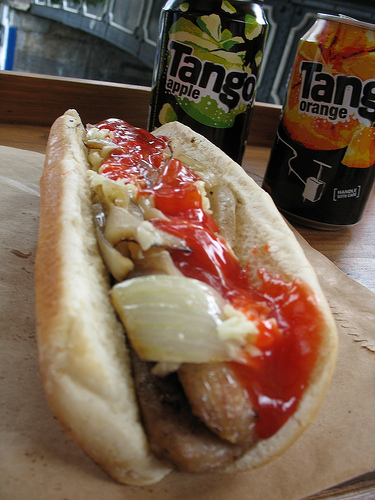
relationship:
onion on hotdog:
[111, 274, 259, 362] [32, 108, 338, 488]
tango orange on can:
[296, 57, 363, 124] [270, 10, 354, 245]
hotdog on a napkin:
[32, 102, 344, 488] [323, 251, 357, 482]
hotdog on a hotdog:
[32, 108, 338, 488] [32, 108, 338, 488]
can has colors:
[145, 0, 266, 162] [148, 29, 246, 133]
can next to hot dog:
[147, 0, 270, 167] [38, 101, 327, 488]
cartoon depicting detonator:
[274, 130, 331, 203] [302, 160, 331, 202]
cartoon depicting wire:
[274, 130, 331, 203] [274, 129, 305, 183]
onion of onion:
[111, 274, 259, 362] [111, 272, 252, 362]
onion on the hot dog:
[111, 272, 252, 362] [38, 101, 327, 488]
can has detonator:
[255, 7, 373, 229] [299, 163, 331, 209]